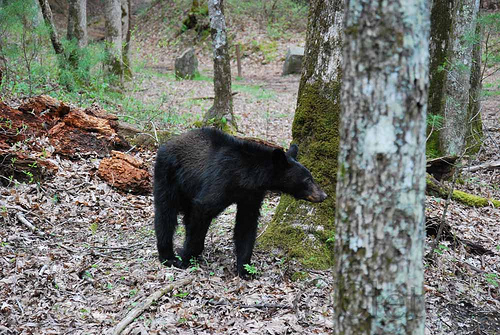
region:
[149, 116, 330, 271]
bear on the leaves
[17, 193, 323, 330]
leaves on the ground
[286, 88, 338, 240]
green plants on the tree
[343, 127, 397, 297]
bark on the tree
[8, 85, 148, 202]
reddish wooden on the leaves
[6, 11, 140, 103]
plants near the wood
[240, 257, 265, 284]
plant near the bear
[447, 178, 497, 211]
plant on the log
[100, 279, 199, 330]
stick on the ground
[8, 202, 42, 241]
twig on the ground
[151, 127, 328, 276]
black bear walking in woods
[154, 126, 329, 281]
bear looking to right side of picture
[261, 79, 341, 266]
moss growing in tree trunk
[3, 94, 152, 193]
rotting dead wood on ground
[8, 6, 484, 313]
animal walking in woodland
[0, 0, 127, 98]
small young trees in the distance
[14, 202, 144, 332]
ground made of dirt, trees, and dead branches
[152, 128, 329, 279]
bear is lean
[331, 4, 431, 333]
blurry tree in foregound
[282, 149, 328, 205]
bear mouth is brown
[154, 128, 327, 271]
A black bear in wilderness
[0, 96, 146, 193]
Brown rotting wood on the ground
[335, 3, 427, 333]
A tree trunk covered with lichens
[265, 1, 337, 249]
A tree trunk covered with green moss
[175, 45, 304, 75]
Two rocks on the ground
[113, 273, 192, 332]
A wooden stick on the ground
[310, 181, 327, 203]
Brown mouth and nose of the bear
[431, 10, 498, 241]
A small green and slender plant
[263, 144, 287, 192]
Outstretched neck of the bear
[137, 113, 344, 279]
this looks like a sun bear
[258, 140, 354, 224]
sun bear has extended long heads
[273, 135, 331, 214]
sun bears have the longest tougues of all mammals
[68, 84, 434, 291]
this bear is in the wild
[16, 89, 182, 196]
this tree is dead and decomposing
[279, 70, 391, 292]
there are lichens growing on this tree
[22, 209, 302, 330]
the groundis covered with detritus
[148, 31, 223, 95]
this tree has been cut with an axe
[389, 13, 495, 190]
these are some sort of pine trees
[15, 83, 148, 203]
this tree is full of nitrogen fixing bacteria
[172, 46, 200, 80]
Tree stump in woods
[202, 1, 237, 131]
Tree in the woods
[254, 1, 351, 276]
Tree with moss on bottom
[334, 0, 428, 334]
Tree trunk in woods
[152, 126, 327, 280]
Black bear standing next to tree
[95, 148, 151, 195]
Large piece of bark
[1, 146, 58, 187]
Large piece of bark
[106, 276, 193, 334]
Large stick laying on ground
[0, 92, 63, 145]
Large piece of bark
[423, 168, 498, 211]
Fallen tree with moss